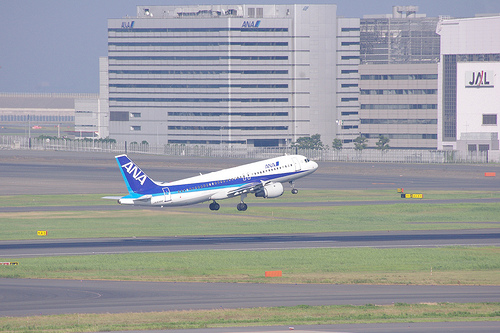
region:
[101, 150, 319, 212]
an airplane getting ready to leave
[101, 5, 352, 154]
a tall building next to the airport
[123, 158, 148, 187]
the name of the company on the tail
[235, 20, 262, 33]
the same name written on the tall building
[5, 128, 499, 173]
the long fence next to the building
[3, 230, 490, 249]
the runway the plane was on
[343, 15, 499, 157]
extra buildings off to the side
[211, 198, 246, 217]
the wheels on the plane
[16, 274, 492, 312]
another road for cars or planes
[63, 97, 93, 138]
a small building to the left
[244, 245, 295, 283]
An orange symbol on the grass.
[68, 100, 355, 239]
The plane is taking off.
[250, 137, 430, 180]
The fence is in front of the plane.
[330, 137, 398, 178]
The fence is white.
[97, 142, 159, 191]
The word ana is on the tail of the plane.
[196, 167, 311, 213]
The wheels are still out.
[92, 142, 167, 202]
The tail is two different color blues.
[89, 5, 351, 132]
The building is to the left of the plane.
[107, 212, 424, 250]
The shadow is on the street.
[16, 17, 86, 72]
The sky is grey.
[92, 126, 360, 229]
The plane is airborne.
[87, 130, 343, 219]
The plane is blue and white.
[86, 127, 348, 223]
The plane is a commercial jet.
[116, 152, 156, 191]
The plane's brand is ANA.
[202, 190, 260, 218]
The landing gear are visible.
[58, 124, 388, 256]
The plane is lifting off.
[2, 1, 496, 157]
Buildings are next to the runway.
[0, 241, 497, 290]
Grass is next to the runway.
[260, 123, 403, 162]
Trees are in front of the buildings.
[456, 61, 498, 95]
The letters JXL are on the building.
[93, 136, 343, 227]
a plane taking off from runway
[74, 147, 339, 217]
a blue and white plane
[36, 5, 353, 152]
a large building with several levels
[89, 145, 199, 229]
the rear wing of a plane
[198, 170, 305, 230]
the landing gear on a plane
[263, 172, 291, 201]
the engine on a plane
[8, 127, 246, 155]
a tall metal fence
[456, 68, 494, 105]
lettering on a white building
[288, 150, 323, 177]
the nose of a airplane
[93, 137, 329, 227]
a airplane with white lettering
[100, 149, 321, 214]
blue and white airplane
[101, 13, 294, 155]
nine floor commercial building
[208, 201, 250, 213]
four black wheels of airplane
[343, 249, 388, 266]
patch of green grass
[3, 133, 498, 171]
long metal fence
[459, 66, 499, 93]
black and red sign on front of building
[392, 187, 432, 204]
yellow and black object on green field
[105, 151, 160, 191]
blue and white tail of airplane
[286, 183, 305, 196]
front wheel of airplane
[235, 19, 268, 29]
blue and grey sign on building